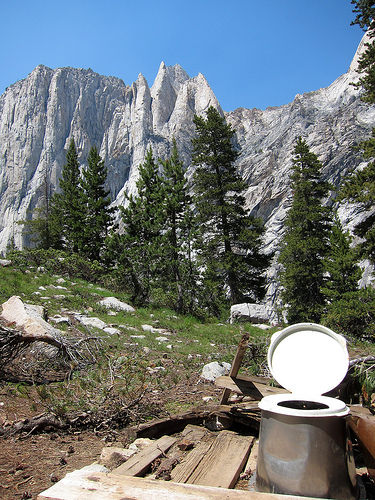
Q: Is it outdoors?
A: Yes, it is outdoors.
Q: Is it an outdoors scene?
A: Yes, it is outdoors.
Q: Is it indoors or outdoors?
A: It is outdoors.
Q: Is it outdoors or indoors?
A: It is outdoors.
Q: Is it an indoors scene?
A: No, it is outdoors.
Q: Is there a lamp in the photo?
A: No, there are no lamps.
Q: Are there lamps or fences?
A: No, there are no lamps or fences.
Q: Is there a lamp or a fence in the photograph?
A: No, there are no lamps or fences.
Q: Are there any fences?
A: No, there are no fences.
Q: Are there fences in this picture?
A: No, there are no fences.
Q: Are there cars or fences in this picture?
A: No, there are no fences or cars.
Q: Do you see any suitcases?
A: No, there are no suitcases.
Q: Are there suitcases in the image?
A: No, there are no suitcases.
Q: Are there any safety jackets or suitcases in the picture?
A: No, there are no suitcases or safety jackets.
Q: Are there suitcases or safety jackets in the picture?
A: No, there are no suitcases or safety jackets.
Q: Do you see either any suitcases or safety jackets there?
A: No, there are no suitcases or safety jackets.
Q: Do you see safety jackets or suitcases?
A: No, there are no suitcases or safety jackets.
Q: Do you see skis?
A: No, there are no skis.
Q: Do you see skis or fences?
A: No, there are no skis or fences.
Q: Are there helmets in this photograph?
A: No, there are no helmets.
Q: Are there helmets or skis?
A: No, there are no helmets or skis.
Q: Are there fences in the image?
A: No, there are no fences.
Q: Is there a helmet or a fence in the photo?
A: No, there are no fences or helmets.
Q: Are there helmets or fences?
A: No, there are no fences or helmets.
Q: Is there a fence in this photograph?
A: No, there are no fences.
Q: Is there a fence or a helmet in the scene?
A: No, there are no fences or helmets.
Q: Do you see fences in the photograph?
A: No, there are no fences.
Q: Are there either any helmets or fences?
A: No, there are no fences or helmets.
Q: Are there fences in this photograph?
A: No, there are no fences.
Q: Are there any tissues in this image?
A: No, there are no tissues.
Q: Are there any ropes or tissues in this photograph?
A: No, there are no tissues or ropes.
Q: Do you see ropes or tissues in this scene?
A: No, there are no tissues or ropes.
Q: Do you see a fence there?
A: No, there are no fences.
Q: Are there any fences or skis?
A: No, there are no fences or skis.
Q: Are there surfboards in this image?
A: No, there are no surfboards.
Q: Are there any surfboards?
A: No, there are no surfboards.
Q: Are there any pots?
A: Yes, there is a pot.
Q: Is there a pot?
A: Yes, there is a pot.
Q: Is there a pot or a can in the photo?
A: Yes, there is a pot.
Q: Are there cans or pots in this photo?
A: Yes, there is a pot.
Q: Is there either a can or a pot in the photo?
A: Yes, there is a pot.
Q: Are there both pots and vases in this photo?
A: No, there is a pot but no vases.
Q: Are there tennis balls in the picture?
A: No, there are no tennis balls.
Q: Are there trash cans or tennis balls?
A: No, there are no tennis balls or trash cans.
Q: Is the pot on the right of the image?
A: Yes, the pot is on the right of the image.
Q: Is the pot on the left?
A: No, the pot is on the right of the image.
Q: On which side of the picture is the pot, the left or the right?
A: The pot is on the right of the image.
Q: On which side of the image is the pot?
A: The pot is on the right of the image.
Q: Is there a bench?
A: No, there are no benches.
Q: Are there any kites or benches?
A: No, there are no benches or kites.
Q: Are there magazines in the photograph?
A: No, there are no magazines.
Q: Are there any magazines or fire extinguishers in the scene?
A: No, there are no magazines or fire extinguishers.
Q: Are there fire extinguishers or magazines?
A: No, there are no magazines or fire extinguishers.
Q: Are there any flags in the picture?
A: No, there are no flags.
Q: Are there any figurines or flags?
A: No, there are no flags or figurines.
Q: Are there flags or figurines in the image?
A: No, there are no flags or figurines.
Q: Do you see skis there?
A: No, there are no skis.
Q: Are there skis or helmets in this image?
A: No, there are no skis or helmets.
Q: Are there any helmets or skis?
A: No, there are no skis or helmets.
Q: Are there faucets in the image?
A: No, there are no faucets.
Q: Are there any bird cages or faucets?
A: No, there are no faucets or bird cages.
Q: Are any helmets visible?
A: No, there are no helmets.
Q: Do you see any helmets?
A: No, there are no helmets.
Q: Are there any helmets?
A: No, there are no helmets.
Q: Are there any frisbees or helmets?
A: No, there are no helmets or frisbees.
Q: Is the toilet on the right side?
A: Yes, the toilet is on the right of the image.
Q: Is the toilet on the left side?
A: No, the toilet is on the right of the image.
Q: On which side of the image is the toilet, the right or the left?
A: The toilet is on the right of the image.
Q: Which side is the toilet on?
A: The toilet is on the right of the image.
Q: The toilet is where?
A: The toilet is in the field.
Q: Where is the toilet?
A: The toilet is in the field.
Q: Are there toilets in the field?
A: Yes, there is a toilet in the field.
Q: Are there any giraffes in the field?
A: No, there is a toilet in the field.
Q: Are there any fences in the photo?
A: No, there are no fences.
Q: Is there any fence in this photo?
A: No, there are no fences.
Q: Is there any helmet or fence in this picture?
A: No, there are no fences or helmets.